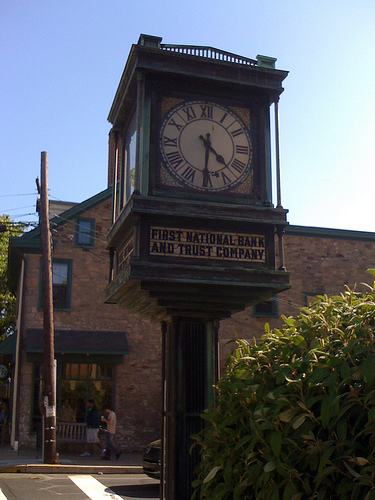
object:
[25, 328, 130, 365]
canopy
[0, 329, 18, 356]
canopy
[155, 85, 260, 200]
clock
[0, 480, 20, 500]
street corner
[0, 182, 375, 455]
building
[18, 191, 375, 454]
brick wall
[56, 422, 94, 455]
bench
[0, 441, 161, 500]
ground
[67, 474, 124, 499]
line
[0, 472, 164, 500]
road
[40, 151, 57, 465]
pole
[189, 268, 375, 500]
bush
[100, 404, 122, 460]
man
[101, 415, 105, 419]
drink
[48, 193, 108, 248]
trim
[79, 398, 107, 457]
pedestrians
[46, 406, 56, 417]
paper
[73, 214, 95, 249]
window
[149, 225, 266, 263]
signs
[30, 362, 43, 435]
window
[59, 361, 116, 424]
window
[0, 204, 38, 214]
wires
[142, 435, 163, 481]
car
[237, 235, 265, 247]
bank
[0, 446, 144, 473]
sidewalk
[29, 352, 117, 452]
storefront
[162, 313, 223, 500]
light post